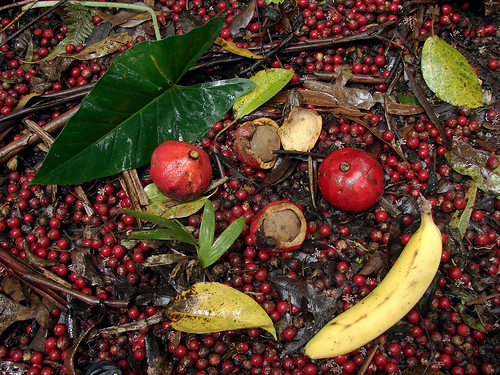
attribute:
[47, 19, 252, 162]
leaf — large, green, heart shaped, big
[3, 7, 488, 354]
ground — red, coffee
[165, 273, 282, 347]
leaf — yellow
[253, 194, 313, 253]
nut — red, open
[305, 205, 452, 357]
banana — yellow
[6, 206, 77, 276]
berries — red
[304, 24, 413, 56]
twigs — brown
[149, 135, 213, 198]
pomegranate — red, broken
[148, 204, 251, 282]
plant — growing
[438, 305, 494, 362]
coffee — red